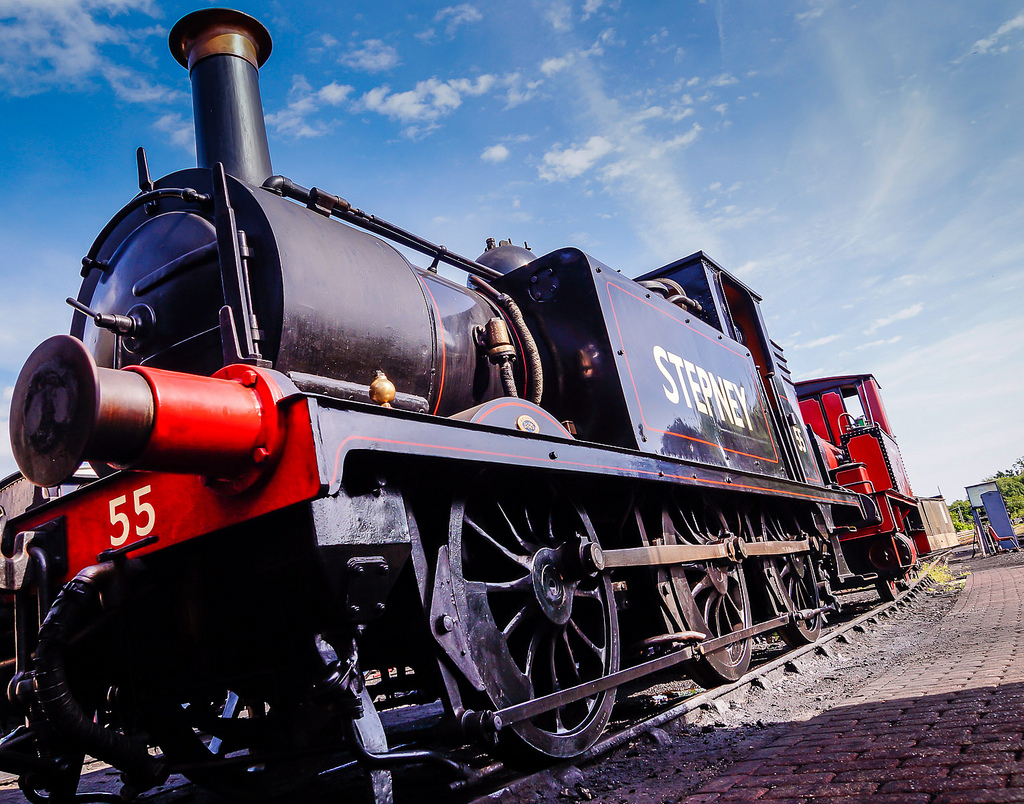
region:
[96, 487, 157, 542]
The number 55 on the front of the train.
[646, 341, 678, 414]
The letter S on the side of the train.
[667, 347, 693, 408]
The letter T on the side of the train.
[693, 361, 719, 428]
The letter R on the side of the train.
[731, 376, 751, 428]
The letter Y on the side of the train.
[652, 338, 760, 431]
The word STERKEY on the side of the train.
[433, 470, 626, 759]
The first wheel of the train.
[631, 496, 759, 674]
The middle wheel of the train.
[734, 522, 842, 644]
The back wheel of the train.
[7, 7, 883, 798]
Steam engine on railroad tracks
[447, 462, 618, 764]
Wheel on a steam engine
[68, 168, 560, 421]
Boiler on a steam train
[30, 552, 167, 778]
Brake lines on a steam train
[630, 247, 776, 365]
Cab on a steam train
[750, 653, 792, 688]
Railroad tie under train track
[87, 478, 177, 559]
white numbers on a train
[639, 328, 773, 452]
white letters on a train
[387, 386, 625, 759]
a large black wheel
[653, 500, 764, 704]
a large black wheel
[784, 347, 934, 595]
a red caboose on a train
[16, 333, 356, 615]
a red bumper on a train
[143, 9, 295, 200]
a black and gold smokestack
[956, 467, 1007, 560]
a small white sign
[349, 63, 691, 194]
the sky has white fluffy clouds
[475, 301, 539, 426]
a gold lever on a train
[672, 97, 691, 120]
a white fluffy cloud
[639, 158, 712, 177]
a white fluffy cloud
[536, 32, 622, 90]
a white fluffy cloud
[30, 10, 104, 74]
a white fluffy cloud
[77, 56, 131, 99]
a white fluffy cloud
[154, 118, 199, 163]
a white fluffy cloud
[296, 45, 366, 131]
a white fluffy cloud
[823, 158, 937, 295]
a white fluffy cloud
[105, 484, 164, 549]
white numbers on the train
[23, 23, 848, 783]
black train engine car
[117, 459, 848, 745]
wheels on the engine car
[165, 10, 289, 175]
steam pipe on the train engine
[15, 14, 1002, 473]
blue sky with scattered clouds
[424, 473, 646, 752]
part of a train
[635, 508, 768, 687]
part of a train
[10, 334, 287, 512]
part of a train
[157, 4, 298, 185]
part of a train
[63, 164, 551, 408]
part of a train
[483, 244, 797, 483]
part of a train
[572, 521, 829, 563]
part of a train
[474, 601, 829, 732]
part of a train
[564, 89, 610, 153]
a white fluffy cloud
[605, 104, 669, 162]
a white fluffy cloud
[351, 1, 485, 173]
a white fluffy cloud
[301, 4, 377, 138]
a white fluffy cloud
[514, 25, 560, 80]
a white fluffy cloud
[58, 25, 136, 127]
a white fluffy cloud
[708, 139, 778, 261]
a white fluffy cloud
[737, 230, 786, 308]
a white fluffy cloud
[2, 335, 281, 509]
The bumper on the black train enginge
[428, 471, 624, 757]
The black front wheel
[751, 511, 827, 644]
The back wheel of the train